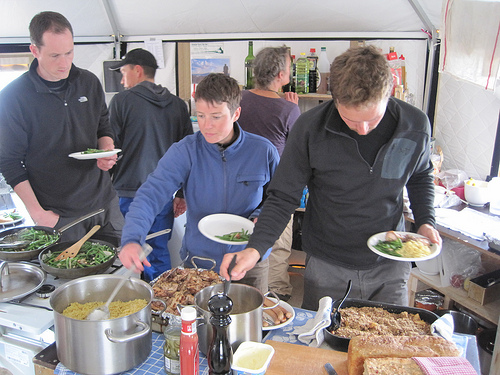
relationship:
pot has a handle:
[47, 273, 154, 375] [104, 322, 152, 342]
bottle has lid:
[178, 305, 201, 374] [181, 305, 196, 322]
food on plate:
[216, 228, 254, 243] [198, 212, 258, 246]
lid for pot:
[0, 260, 45, 305] [47, 273, 154, 375]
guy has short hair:
[1, 12, 122, 244] [29, 12, 74, 52]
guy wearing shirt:
[218, 48, 442, 309] [243, 98, 440, 273]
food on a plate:
[398, 242, 428, 259] [367, 231, 441, 264]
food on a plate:
[386, 232, 422, 244] [367, 231, 441, 264]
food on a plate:
[371, 237, 403, 254] [367, 231, 441, 264]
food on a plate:
[216, 228, 254, 243] [198, 212, 258, 246]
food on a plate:
[81, 149, 108, 154] [69, 150, 122, 161]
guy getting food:
[218, 48, 442, 309] [206, 289, 249, 309]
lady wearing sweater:
[118, 74, 280, 299] [119, 123, 282, 273]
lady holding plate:
[118, 74, 280, 299] [198, 212, 258, 246]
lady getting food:
[118, 74, 280, 299] [64, 300, 145, 321]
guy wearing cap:
[108, 48, 194, 283] [103, 48, 159, 70]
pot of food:
[47, 273, 154, 375] [64, 300, 145, 321]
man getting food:
[215, 45, 443, 311] [206, 289, 249, 309]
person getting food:
[119, 74, 278, 296] [64, 300, 145, 321]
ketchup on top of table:
[177, 307, 199, 375] [1, 173, 477, 374]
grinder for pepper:
[208, 290, 231, 374] [208, 290, 232, 374]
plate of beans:
[198, 212, 258, 246] [217, 229, 252, 245]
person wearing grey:
[1, 12, 124, 249] [2, 60, 117, 214]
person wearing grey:
[105, 49, 192, 283] [102, 82, 190, 199]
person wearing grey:
[237, 48, 301, 251] [239, 85, 302, 158]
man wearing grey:
[215, 45, 443, 311] [246, 100, 437, 269]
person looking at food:
[237, 48, 301, 251] [292, 54, 310, 96]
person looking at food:
[237, 48, 301, 251] [317, 47, 329, 95]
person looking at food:
[237, 48, 301, 251] [307, 49, 319, 95]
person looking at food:
[237, 48, 301, 251] [285, 56, 296, 96]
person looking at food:
[237, 48, 301, 251] [388, 52, 402, 97]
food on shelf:
[388, 52, 402, 97] [241, 40, 425, 101]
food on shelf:
[317, 47, 329, 95] [241, 40, 425, 101]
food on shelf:
[307, 49, 319, 95] [241, 40, 425, 101]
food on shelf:
[292, 54, 310, 96] [241, 40, 425, 101]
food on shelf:
[285, 56, 296, 96] [241, 40, 425, 101]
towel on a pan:
[429, 312, 453, 342] [317, 299, 445, 353]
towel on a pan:
[288, 297, 333, 349] [317, 299, 445, 353]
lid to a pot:
[181, 305, 196, 322] [47, 273, 154, 375]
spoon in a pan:
[55, 223, 101, 265] [37, 227, 173, 278]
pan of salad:
[37, 227, 173, 278] [46, 243, 111, 268]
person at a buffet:
[1, 12, 124, 249] [0, 173, 500, 374]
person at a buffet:
[119, 74, 278, 296] [0, 173, 500, 374]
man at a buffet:
[215, 45, 443, 311] [0, 173, 500, 374]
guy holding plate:
[1, 12, 122, 244] [69, 150, 122, 161]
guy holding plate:
[218, 48, 442, 309] [367, 231, 441, 264]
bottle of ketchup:
[178, 305, 201, 374] [177, 307, 199, 375]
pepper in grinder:
[208, 290, 232, 374] [208, 290, 231, 374]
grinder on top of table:
[208, 290, 231, 374] [1, 173, 477, 374]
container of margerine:
[228, 339, 276, 374] [239, 349, 266, 370]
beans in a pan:
[0, 229, 58, 250] [1, 207, 108, 262]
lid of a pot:
[181, 305, 196, 322] [47, 273, 154, 375]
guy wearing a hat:
[108, 43, 194, 282] [104, 49, 160, 74]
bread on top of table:
[348, 334, 477, 373] [1, 173, 477, 374]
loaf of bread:
[362, 359, 475, 374] [348, 334, 477, 373]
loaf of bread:
[348, 334, 461, 373] [348, 334, 477, 373]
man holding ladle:
[219, 45, 442, 311] [219, 254, 237, 313]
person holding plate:
[1, 12, 124, 249] [69, 150, 122, 161]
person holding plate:
[119, 74, 278, 296] [198, 212, 258, 246]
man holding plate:
[215, 45, 443, 311] [367, 231, 441, 264]